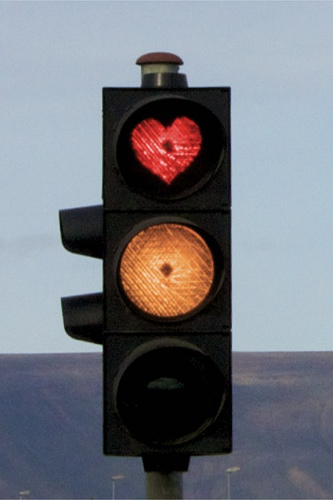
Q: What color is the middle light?
A: Orange.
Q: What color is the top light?
A: Red.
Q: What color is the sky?
A: Grey.